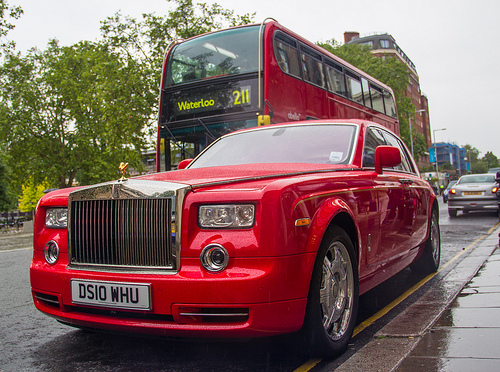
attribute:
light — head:
[42, 200, 69, 232]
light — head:
[205, 205, 260, 230]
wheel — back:
[417, 199, 449, 277]